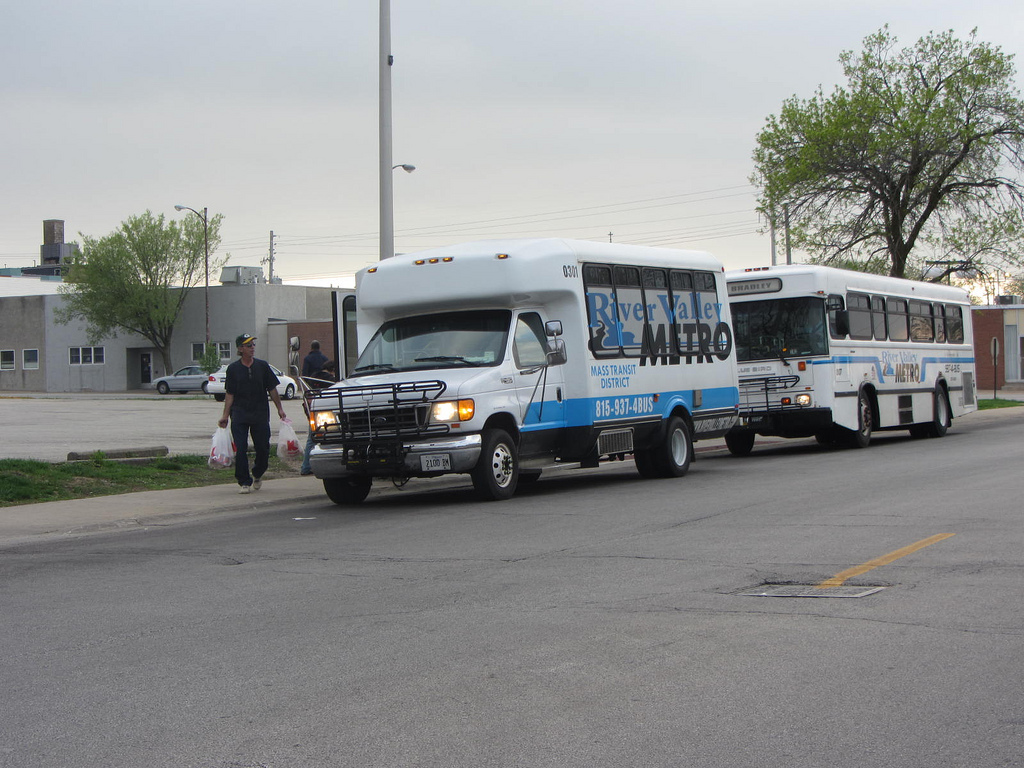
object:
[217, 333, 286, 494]
man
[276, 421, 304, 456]
bags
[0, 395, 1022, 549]
sidewalk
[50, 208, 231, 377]
tree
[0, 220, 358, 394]
building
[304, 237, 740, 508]
buses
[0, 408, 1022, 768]
road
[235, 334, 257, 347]
hat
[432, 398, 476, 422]
lights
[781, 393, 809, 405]
lights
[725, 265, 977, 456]
bus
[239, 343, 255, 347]
glasses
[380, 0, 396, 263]
pole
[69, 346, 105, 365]
windows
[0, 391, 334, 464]
parking lot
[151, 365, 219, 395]
car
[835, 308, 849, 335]
mirror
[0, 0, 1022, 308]
sky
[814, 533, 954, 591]
line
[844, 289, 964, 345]
windows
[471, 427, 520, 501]
tire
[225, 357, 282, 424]
shirt